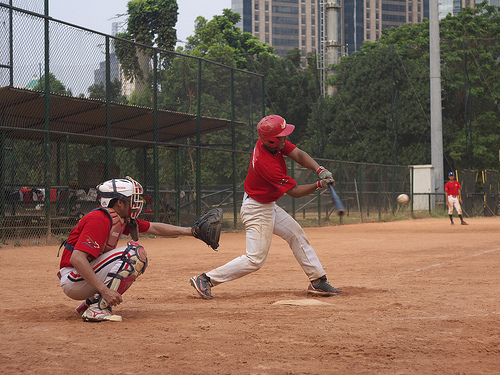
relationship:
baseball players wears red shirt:
[189, 114, 349, 300] [236, 131, 306, 210]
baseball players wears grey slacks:
[189, 114, 349, 300] [207, 196, 329, 289]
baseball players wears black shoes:
[189, 114, 349, 300] [305, 272, 354, 315]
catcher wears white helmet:
[55, 174, 224, 323] [87, 174, 148, 218]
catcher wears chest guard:
[55, 174, 224, 323] [98, 204, 143, 275]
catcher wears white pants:
[55, 174, 224, 323] [46, 235, 143, 321]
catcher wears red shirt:
[55, 174, 224, 323] [65, 197, 141, 269]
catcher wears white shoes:
[50, 161, 237, 313] [75, 292, 127, 323]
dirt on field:
[349, 221, 469, 362] [20, 216, 488, 373]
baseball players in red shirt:
[189, 114, 349, 300] [243, 139, 297, 204]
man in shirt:
[442, 171, 468, 225] [444, 180, 464, 191]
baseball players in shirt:
[189, 114, 349, 300] [241, 138, 291, 203]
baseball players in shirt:
[189, 114, 349, 300] [248, 139, 294, 198]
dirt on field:
[11, 218, 482, 362] [0, 212, 499, 375]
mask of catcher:
[100, 171, 145, 236] [58, 179, 232, 326]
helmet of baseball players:
[257, 113, 297, 152] [189, 114, 349, 300]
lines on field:
[394, 246, 484, 311] [20, 216, 488, 373]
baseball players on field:
[53, 101, 363, 319] [13, 199, 474, 373]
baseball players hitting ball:
[189, 114, 349, 300] [398, 194, 410, 204]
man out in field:
[444, 171, 469, 225] [6, 203, 483, 360]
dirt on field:
[11, 218, 482, 362] [4, 212, 477, 343]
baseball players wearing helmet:
[189, 114, 349, 300] [255, 114, 295, 153]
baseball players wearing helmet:
[189, 114, 349, 300] [259, 113, 294, 144]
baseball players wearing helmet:
[189, 114, 349, 300] [253, 104, 294, 142]